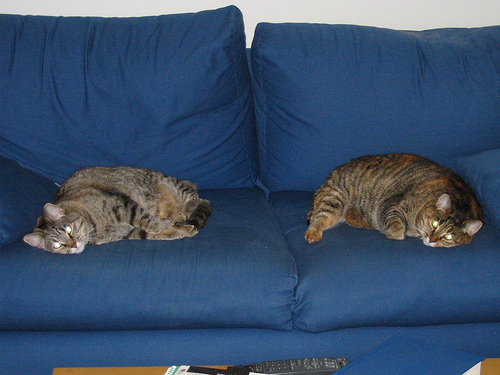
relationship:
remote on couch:
[276, 352, 321, 368] [137, 28, 275, 168]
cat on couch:
[64, 184, 181, 241] [137, 28, 275, 168]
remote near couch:
[276, 352, 321, 368] [137, 28, 275, 168]